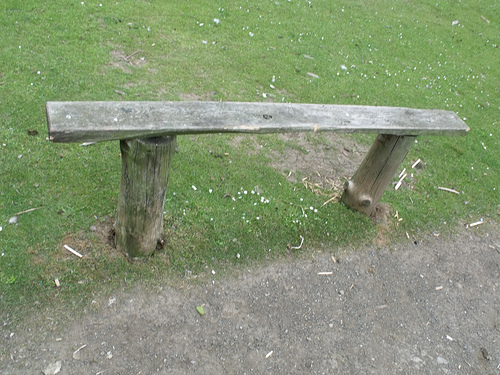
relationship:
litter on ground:
[284, 222, 317, 260] [230, 180, 369, 324]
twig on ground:
[264, 205, 322, 250] [230, 180, 369, 324]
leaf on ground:
[387, 164, 458, 233] [230, 180, 369, 324]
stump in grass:
[113, 135, 179, 260] [208, 12, 341, 86]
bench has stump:
[37, 89, 477, 258] [110, 122, 194, 273]